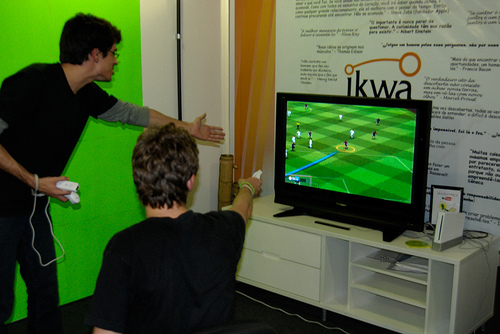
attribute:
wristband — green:
[237, 172, 266, 195]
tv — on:
[266, 87, 436, 244]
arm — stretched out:
[89, 87, 229, 144]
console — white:
[429, 206, 469, 251]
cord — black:
[165, 8, 199, 120]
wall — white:
[273, 2, 498, 244]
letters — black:
[348, 65, 418, 100]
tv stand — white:
[215, 186, 495, 331]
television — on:
[285, 98, 412, 208]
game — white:
[50, 174, 86, 208]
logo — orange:
[337, 46, 424, 95]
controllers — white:
[50, 174, 86, 214]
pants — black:
[2, 197, 65, 331]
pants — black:
[2, 194, 72, 315]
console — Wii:
[428, 204, 471, 249]